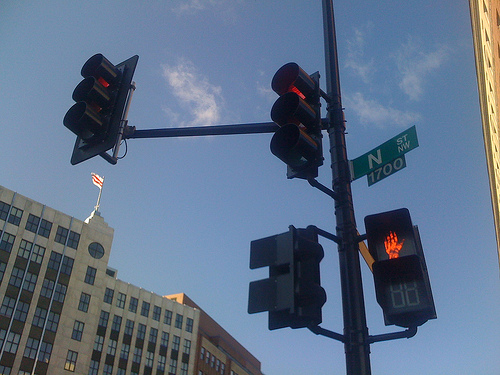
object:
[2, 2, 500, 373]
sky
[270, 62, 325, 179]
light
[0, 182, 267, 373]
building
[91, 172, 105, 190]
flag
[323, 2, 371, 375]
pole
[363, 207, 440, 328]
signals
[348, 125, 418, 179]
sign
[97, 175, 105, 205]
pole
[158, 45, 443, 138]
cloud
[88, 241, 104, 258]
window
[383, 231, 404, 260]
hand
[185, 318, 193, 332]
windows